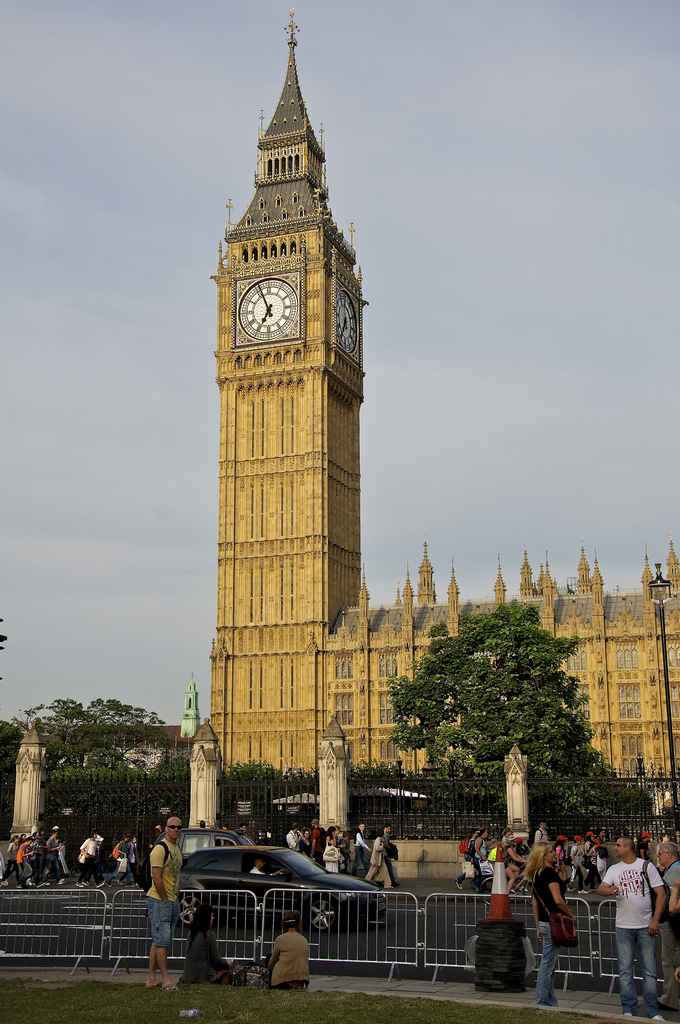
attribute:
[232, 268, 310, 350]
clock — white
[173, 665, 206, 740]
church — small, green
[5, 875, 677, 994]
fence — metal, silver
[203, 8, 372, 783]
tower — tall, brown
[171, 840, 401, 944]
car — black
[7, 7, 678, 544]
sky — blue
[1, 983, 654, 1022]
grass — green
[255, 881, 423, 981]
rail — grey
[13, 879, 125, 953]
road — grey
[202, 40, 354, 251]
tower — brown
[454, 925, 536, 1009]
can — black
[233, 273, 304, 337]
clock — black, white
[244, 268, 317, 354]
clock — white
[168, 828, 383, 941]
car — black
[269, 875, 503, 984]
rail — gray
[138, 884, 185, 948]
shorts — blue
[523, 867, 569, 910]
shirt — black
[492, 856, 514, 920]
cone — orange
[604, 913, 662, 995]
jeans — blue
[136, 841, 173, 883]
backpack — black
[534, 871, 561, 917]
t-shirt — white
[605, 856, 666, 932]
t-shirt — white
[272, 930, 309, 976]
jacket — brown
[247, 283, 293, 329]
dials — black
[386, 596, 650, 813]
tree — green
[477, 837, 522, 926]
cone — orange, white